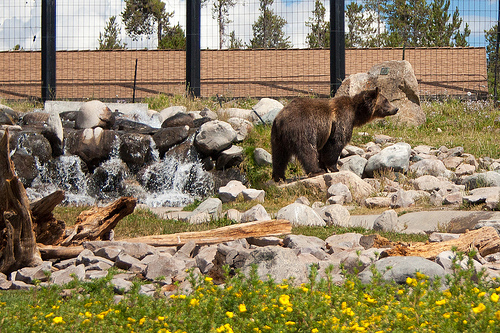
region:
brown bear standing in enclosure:
[268, 83, 398, 189]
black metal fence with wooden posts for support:
[4, 0, 499, 103]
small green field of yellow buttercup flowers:
[16, 256, 496, 330]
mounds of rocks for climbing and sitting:
[0, 98, 495, 285]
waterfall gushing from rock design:
[21, 136, 228, 214]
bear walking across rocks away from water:
[268, 78, 410, 181]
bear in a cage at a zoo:
[270, 84, 404, 179]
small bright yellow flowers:
[0, 267, 499, 331]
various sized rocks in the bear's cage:
[1, 97, 497, 297]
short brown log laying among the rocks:
[370, 225, 499, 263]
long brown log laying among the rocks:
[39, 218, 291, 260]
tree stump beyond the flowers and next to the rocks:
[0, 127, 49, 269]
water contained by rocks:
[26, 155, 204, 209]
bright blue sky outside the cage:
[351, 0, 498, 45]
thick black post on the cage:
[185, 0, 202, 94]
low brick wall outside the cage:
[0, 47, 486, 94]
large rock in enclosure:
[360, 257, 446, 287]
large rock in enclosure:
[438, 249, 488, 283]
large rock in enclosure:
[342, 245, 387, 270]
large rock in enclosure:
[228, 243, 303, 285]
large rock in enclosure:
[144, 250, 179, 279]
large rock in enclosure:
[52, 263, 88, 288]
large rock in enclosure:
[193, 118, 234, 151]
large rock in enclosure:
[363, 142, 414, 175]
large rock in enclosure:
[328, 181, 354, 203]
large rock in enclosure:
[458, 168, 495, 187]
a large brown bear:
[270, 86, 400, 180]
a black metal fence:
[4, 0, 498, 105]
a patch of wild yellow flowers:
[0, 273, 499, 330]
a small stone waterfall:
[30, 136, 251, 203]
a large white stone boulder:
[273, 203, 324, 225]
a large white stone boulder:
[365, 141, 408, 173]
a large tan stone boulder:
[333, 58, 424, 130]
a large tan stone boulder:
[193, 119, 236, 156]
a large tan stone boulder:
[78, 100, 114, 128]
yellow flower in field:
[488, 290, 498, 301]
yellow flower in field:
[476, 289, 487, 297]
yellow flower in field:
[477, 301, 486, 309]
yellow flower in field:
[471, 305, 483, 314]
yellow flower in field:
[276, 295, 291, 304]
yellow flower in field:
[340, 300, 348, 308]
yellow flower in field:
[188, 297, 200, 308]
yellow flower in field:
[53, 315, 63, 325]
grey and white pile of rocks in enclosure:
[3, 98, 488, 289]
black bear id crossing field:
[259, 81, 404, 191]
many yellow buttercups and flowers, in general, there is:
[31, 231, 498, 326]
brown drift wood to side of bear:
[2, 128, 292, 273]